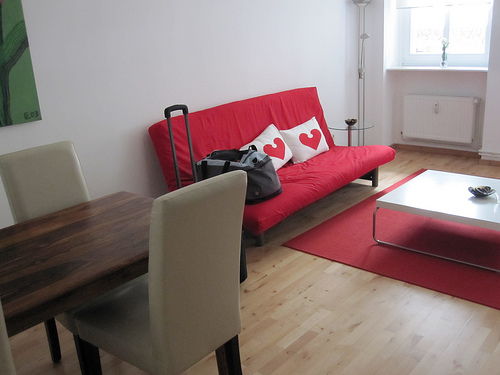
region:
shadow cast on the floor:
[371, 210, 496, 291]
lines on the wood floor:
[265, 291, 363, 352]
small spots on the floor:
[236, 287, 299, 339]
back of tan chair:
[148, 150, 258, 328]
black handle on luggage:
[152, 85, 202, 128]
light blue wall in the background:
[102, 23, 250, 76]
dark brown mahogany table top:
[23, 212, 118, 275]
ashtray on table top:
[449, 160, 494, 200]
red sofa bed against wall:
[155, 87, 382, 227]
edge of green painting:
[15, 47, 82, 134]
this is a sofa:
[256, 90, 348, 208]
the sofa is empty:
[285, 92, 342, 189]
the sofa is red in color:
[330, 144, 358, 176]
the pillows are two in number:
[277, 122, 318, 159]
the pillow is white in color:
[285, 120, 320, 155]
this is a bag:
[212, 147, 253, 166]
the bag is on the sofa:
[218, 148, 255, 160]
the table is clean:
[41, 204, 111, 266]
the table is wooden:
[70, 211, 129, 261]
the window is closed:
[406, 10, 482, 60]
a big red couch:
[118, 50, 446, 260]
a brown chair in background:
[81, 163, 395, 372]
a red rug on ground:
[332, 153, 493, 306]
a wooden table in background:
[5, 192, 337, 304]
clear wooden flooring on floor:
[272, 262, 425, 369]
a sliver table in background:
[384, 165, 496, 232]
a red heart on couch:
[272, 118, 359, 168]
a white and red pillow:
[268, 113, 380, 184]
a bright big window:
[385, 13, 497, 75]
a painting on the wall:
[0, 11, 33, 119]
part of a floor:
[311, 290, 361, 334]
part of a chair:
[163, 275, 194, 320]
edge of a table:
[6, 284, 49, 318]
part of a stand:
[390, 235, 430, 259]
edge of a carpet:
[369, 262, 411, 285]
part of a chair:
[276, 195, 295, 215]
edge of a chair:
[142, 298, 180, 358]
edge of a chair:
[133, 260, 170, 320]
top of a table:
[43, 242, 80, 286]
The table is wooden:
[2, 177, 178, 316]